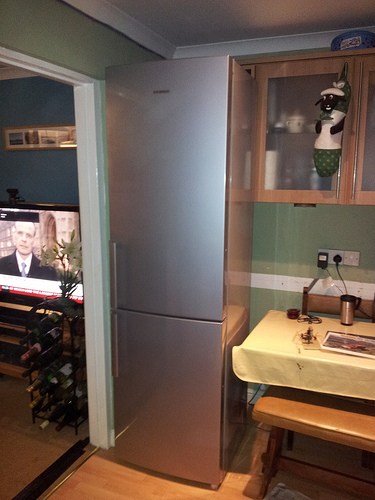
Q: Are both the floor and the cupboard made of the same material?
A: Yes, both the floor and the cupboard are made of wood.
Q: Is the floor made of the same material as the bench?
A: Yes, both the floor and the bench are made of wood.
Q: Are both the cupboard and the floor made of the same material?
A: Yes, both the cupboard and the floor are made of wood.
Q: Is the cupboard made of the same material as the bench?
A: Yes, both the cupboard and the bench are made of wood.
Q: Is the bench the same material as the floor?
A: Yes, both the bench and the floor are made of wood.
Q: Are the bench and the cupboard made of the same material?
A: Yes, both the bench and the cupboard are made of wood.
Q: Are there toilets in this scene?
A: No, there are no toilets.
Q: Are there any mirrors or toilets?
A: No, there are no toilets or mirrors.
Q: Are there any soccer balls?
A: No, there are no soccer balls.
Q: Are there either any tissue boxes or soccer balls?
A: No, there are no soccer balls or tissue boxes.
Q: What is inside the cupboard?
A: The dishes are inside the cupboard.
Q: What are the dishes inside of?
A: The dishes are inside the cupboard.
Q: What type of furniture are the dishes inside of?
A: The dishes are inside the cupboard.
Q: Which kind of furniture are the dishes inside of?
A: The dishes are inside the cupboard.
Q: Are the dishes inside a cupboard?
A: Yes, the dishes are inside a cupboard.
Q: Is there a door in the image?
A: Yes, there are doors.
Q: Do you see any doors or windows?
A: Yes, there are doors.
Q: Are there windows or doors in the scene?
A: Yes, there are doors.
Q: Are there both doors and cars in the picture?
A: No, there are doors but no cars.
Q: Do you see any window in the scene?
A: No, there are no windows.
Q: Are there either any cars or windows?
A: No, there are no windows or cars.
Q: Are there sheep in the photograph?
A: Yes, there is a sheep.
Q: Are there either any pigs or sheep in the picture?
A: Yes, there is a sheep.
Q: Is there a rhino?
A: No, there are no rhinos.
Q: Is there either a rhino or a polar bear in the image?
A: No, there are no rhinos or polar bears.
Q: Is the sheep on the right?
A: Yes, the sheep is on the right of the image.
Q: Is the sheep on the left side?
A: No, the sheep is on the right of the image.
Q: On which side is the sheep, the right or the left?
A: The sheep is on the right of the image.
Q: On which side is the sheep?
A: The sheep is on the right of the image.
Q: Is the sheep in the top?
A: Yes, the sheep is in the top of the image.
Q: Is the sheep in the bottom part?
A: No, the sheep is in the top of the image.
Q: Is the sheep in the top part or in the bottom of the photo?
A: The sheep is in the top of the image.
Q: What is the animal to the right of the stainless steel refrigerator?
A: The animal is a sheep.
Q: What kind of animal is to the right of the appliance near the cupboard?
A: The animal is a sheep.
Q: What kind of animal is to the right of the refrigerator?
A: The animal is a sheep.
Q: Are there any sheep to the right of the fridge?
A: Yes, there is a sheep to the right of the fridge.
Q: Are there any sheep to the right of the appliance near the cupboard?
A: Yes, there is a sheep to the right of the fridge.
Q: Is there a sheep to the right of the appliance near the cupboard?
A: Yes, there is a sheep to the right of the fridge.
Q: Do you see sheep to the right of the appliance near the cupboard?
A: Yes, there is a sheep to the right of the fridge.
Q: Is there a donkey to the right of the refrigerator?
A: No, there is a sheep to the right of the refrigerator.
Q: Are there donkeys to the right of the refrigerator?
A: No, there is a sheep to the right of the refrigerator.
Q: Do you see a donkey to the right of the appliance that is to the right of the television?
A: No, there is a sheep to the right of the refrigerator.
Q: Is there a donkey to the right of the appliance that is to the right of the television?
A: No, there is a sheep to the right of the refrigerator.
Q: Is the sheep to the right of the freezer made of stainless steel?
A: Yes, the sheep is to the right of the refrigerator.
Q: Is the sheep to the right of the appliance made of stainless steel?
A: Yes, the sheep is to the right of the refrigerator.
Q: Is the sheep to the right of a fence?
A: No, the sheep is to the right of the refrigerator.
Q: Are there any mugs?
A: Yes, there is a mug.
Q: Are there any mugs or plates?
A: Yes, there is a mug.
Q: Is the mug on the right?
A: Yes, the mug is on the right of the image.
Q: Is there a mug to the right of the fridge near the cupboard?
A: Yes, there is a mug to the right of the freezer.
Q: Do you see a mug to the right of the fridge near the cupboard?
A: Yes, there is a mug to the right of the freezer.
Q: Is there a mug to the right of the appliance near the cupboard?
A: Yes, there is a mug to the right of the freezer.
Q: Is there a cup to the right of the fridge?
A: No, there is a mug to the right of the fridge.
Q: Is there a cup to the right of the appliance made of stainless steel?
A: No, there is a mug to the right of the fridge.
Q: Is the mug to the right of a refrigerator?
A: Yes, the mug is to the right of a refrigerator.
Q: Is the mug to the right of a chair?
A: No, the mug is to the right of a refrigerator.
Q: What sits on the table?
A: The mug sits on the table.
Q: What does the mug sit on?
A: The mug sits on the table.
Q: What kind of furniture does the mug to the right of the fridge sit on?
A: The mug sits on the table.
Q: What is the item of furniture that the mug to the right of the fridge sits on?
A: The piece of furniture is a table.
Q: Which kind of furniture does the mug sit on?
A: The mug sits on the table.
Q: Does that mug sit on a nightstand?
A: No, the mug sits on a table.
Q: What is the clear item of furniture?
A: The piece of furniture is a cupboard.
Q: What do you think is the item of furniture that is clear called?
A: The piece of furniture is a cupboard.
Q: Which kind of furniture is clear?
A: The furniture is a cupboard.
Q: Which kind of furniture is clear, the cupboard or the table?
A: The cupboard is clear.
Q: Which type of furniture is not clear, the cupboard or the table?
A: The table is not clear.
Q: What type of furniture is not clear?
A: The furniture is a table.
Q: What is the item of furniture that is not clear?
A: The piece of furniture is a table.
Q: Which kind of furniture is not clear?
A: The furniture is a table.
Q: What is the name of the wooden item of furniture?
A: The piece of furniture is a cupboard.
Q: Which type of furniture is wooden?
A: The furniture is a cupboard.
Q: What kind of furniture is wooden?
A: The furniture is a cupboard.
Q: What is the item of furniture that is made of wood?
A: The piece of furniture is a cupboard.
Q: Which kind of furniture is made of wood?
A: The furniture is a cupboard.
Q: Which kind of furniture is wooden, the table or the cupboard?
A: The cupboard is wooden.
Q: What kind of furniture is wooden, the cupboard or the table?
A: The cupboard is wooden.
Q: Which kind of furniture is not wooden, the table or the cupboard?
A: The table is not wooden.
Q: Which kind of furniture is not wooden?
A: The furniture is a table.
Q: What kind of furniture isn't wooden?
A: The furniture is a table.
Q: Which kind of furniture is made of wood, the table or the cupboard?
A: The cupboard is made of wood.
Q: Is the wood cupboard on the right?
A: Yes, the cupboard is on the right of the image.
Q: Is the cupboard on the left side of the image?
A: No, the cupboard is on the right of the image.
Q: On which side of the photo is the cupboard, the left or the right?
A: The cupboard is on the right of the image.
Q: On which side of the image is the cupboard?
A: The cupboard is on the right of the image.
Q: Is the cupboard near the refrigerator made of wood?
A: Yes, the cupboard is made of wood.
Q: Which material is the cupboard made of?
A: The cupboard is made of wood.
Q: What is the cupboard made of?
A: The cupboard is made of wood.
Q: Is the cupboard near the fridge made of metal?
A: No, the cupboard is made of wood.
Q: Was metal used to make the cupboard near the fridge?
A: No, the cupboard is made of wood.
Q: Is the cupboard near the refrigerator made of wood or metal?
A: The cupboard is made of wood.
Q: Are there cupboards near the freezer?
A: Yes, there is a cupboard near the freezer.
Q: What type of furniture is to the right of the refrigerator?
A: The piece of furniture is a cupboard.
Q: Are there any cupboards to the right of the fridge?
A: Yes, there is a cupboard to the right of the fridge.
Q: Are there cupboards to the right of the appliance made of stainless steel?
A: Yes, there is a cupboard to the right of the fridge.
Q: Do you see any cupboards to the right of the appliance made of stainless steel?
A: Yes, there is a cupboard to the right of the fridge.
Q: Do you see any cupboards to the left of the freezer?
A: No, the cupboard is to the right of the freezer.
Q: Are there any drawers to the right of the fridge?
A: No, there is a cupboard to the right of the fridge.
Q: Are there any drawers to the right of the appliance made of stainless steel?
A: No, there is a cupboard to the right of the fridge.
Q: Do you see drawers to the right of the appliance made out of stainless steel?
A: No, there is a cupboard to the right of the fridge.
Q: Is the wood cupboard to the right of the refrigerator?
A: Yes, the cupboard is to the right of the refrigerator.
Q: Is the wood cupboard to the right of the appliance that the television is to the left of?
A: Yes, the cupboard is to the right of the refrigerator.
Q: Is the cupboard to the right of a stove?
A: No, the cupboard is to the right of the refrigerator.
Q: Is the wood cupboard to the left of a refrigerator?
A: No, the cupboard is to the right of a refrigerator.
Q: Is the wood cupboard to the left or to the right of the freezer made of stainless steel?
A: The cupboard is to the right of the refrigerator.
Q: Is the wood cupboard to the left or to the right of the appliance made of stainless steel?
A: The cupboard is to the right of the refrigerator.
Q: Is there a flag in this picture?
A: No, there are no flags.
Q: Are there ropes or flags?
A: No, there are no flags or ropes.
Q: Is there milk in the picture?
A: No, there is no milk.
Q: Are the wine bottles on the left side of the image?
A: Yes, the wine bottles are on the left of the image.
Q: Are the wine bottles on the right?
A: No, the wine bottles are on the left of the image.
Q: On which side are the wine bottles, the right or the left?
A: The wine bottles are on the left of the image.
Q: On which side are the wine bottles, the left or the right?
A: The wine bottles are on the left of the image.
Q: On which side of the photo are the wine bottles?
A: The wine bottles are on the left of the image.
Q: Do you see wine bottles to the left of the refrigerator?
A: Yes, there are wine bottles to the left of the refrigerator.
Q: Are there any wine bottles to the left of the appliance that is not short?
A: Yes, there are wine bottles to the left of the refrigerator.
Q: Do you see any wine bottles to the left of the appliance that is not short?
A: Yes, there are wine bottles to the left of the refrigerator.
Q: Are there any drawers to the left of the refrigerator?
A: No, there are wine bottles to the left of the refrigerator.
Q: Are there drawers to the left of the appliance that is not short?
A: No, there are wine bottles to the left of the refrigerator.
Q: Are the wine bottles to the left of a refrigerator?
A: Yes, the wine bottles are to the left of a refrigerator.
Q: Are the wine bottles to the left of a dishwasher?
A: No, the wine bottles are to the left of a refrigerator.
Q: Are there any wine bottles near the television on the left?
A: Yes, there are wine bottles near the television.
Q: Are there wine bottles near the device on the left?
A: Yes, there are wine bottles near the television.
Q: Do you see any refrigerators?
A: Yes, there is a refrigerator.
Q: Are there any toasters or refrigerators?
A: Yes, there is a refrigerator.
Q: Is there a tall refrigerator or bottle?
A: Yes, there is a tall refrigerator.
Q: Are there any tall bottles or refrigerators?
A: Yes, there is a tall refrigerator.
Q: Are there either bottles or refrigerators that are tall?
A: Yes, the refrigerator is tall.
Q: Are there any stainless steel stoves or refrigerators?
A: Yes, there is a stainless steel refrigerator.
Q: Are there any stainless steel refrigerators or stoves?
A: Yes, there is a stainless steel refrigerator.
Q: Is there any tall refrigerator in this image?
A: Yes, there is a tall refrigerator.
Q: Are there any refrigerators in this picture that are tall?
A: Yes, there is a refrigerator that is tall.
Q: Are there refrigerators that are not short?
A: Yes, there is a tall refrigerator.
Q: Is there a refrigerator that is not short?
A: Yes, there is a tall refrigerator.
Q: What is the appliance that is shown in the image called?
A: The appliance is a refrigerator.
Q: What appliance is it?
A: The appliance is a refrigerator.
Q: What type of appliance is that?
A: This is a refrigerator.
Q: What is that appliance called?
A: This is a refrigerator.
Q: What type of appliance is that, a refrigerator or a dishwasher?
A: This is a refrigerator.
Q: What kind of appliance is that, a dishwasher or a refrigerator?
A: This is a refrigerator.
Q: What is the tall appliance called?
A: The appliance is a refrigerator.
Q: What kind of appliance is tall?
A: The appliance is a refrigerator.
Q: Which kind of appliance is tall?
A: The appliance is a refrigerator.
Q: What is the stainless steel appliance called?
A: The appliance is a refrigerator.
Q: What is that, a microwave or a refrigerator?
A: That is a refrigerator.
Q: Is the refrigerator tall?
A: Yes, the refrigerator is tall.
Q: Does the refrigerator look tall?
A: Yes, the refrigerator is tall.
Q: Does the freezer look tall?
A: Yes, the freezer is tall.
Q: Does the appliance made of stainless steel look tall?
A: Yes, the freezer is tall.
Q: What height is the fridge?
A: The fridge is tall.